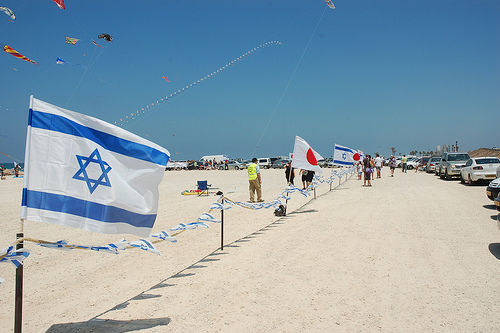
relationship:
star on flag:
[71, 146, 114, 195] [26, 97, 171, 247]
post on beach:
[215, 189, 229, 243] [0, 167, 495, 332]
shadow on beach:
[45, 172, 358, 331] [0, 167, 495, 332]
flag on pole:
[13, 94, 170, 333] [15, 205, 25, 330]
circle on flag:
[306, 149, 316, 169] [293, 138, 322, 174]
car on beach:
[435, 152, 471, 180] [0, 167, 495, 332]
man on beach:
[362, 154, 372, 187] [0, 167, 495, 332]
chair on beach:
[197, 176, 211, 194] [0, 167, 495, 332]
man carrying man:
[357, 154, 373, 184] [362, 154, 372, 187]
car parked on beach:
[456, 157, 498, 187] [6, 167, 495, 328]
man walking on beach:
[362, 154, 372, 187] [6, 167, 495, 328]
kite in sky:
[65, 36, 80, 46] [4, 1, 497, 162]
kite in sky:
[66, 34, 77, 44] [4, 1, 497, 162]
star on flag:
[72, 147, 113, 193] [13, 94, 170, 333]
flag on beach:
[13, 94, 176, 330] [0, 167, 495, 332]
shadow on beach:
[45, 207, 317, 331] [0, 167, 495, 332]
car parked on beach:
[435, 152, 471, 180] [0, 167, 495, 332]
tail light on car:
[472, 164, 487, 170] [457, 155, 496, 184]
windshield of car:
[442, 151, 472, 163] [434, 149, 470, 179]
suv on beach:
[168, 162, 195, 176] [212, 263, 433, 330]